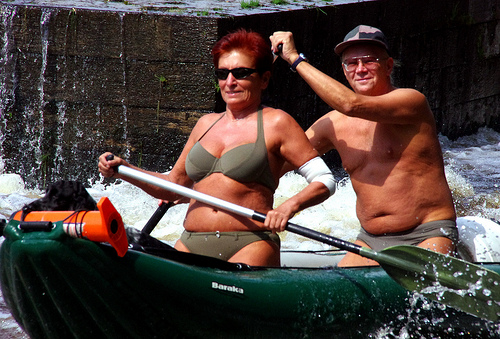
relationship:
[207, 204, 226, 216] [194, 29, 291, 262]
belly button of woman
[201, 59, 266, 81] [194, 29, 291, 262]
sunglasses of woman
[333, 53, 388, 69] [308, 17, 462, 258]
glasses on man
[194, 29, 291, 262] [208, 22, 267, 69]
woman with red hair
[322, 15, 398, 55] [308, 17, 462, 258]
hat on man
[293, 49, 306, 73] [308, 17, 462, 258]
watch on man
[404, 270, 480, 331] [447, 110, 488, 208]
splashes of water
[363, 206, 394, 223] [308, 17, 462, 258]
belly button of man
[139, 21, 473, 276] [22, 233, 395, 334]
people paddling raft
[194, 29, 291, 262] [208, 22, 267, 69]
woman has red hair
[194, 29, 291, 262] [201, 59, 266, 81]
woman wearing sunglasses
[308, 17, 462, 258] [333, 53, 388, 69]
man wearing glasses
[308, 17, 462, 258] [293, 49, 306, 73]
man has watch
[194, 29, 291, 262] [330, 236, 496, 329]
woman holding paddle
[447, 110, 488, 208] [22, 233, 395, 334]
water splashing on raft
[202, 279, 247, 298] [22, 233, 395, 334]
baraka on raft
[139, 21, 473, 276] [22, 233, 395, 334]
couple in raft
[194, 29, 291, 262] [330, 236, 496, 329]
woman with paddle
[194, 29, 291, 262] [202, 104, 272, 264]
woman with swimsuit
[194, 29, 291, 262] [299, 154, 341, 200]
woman with elbow band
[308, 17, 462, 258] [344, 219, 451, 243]
man wearing briefs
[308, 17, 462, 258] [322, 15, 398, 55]
man wearing hat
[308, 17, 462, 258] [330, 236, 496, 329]
man with paddle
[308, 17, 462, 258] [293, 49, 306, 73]
man with watch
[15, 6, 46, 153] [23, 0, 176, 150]
rust on rock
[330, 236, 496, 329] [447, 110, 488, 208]
paddle in water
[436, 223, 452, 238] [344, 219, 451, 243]
logo on briefs